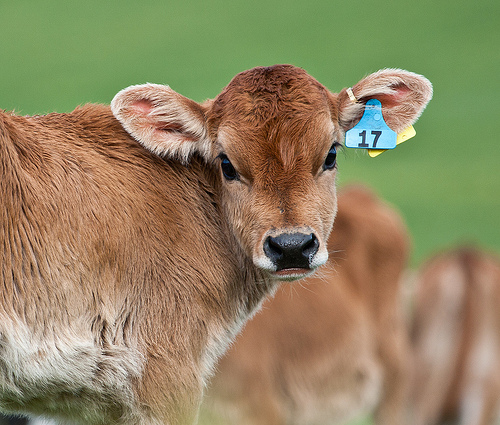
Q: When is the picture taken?
A: Daytime.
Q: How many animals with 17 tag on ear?
A: One.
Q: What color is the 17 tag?
A: Blue.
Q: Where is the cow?
A: Field.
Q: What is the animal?
A: Cow.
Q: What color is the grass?
A: Green.